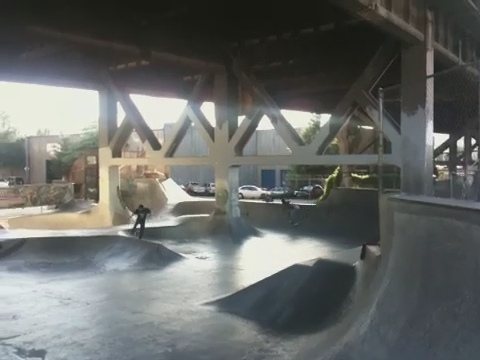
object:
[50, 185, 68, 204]
grass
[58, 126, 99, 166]
tree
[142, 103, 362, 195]
building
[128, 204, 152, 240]
guy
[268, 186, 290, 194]
cars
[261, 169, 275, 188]
door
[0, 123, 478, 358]
park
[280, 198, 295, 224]
person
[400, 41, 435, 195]
beam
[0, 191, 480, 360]
skate park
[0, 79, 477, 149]
sky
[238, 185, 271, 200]
car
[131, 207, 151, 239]
clothing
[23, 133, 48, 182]
building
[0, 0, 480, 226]
structure